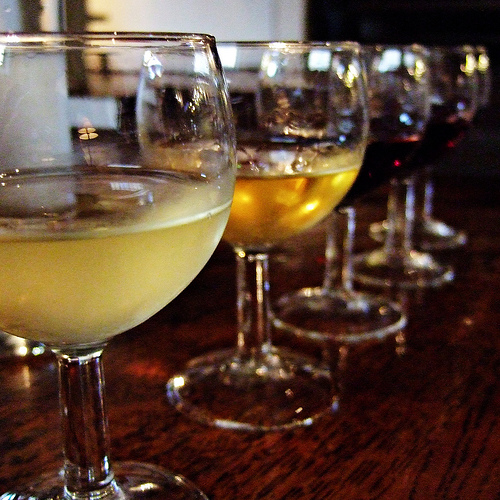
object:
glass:
[2, 30, 238, 498]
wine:
[0, 167, 236, 347]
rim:
[0, 31, 216, 43]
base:
[2, 458, 212, 499]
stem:
[51, 339, 114, 494]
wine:
[150, 146, 368, 251]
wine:
[312, 134, 414, 208]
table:
[1, 131, 499, 499]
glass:
[136, 40, 370, 432]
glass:
[253, 43, 436, 342]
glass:
[341, 43, 454, 288]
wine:
[410, 118, 471, 178]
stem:
[236, 246, 271, 364]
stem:
[323, 204, 357, 289]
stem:
[389, 178, 412, 251]